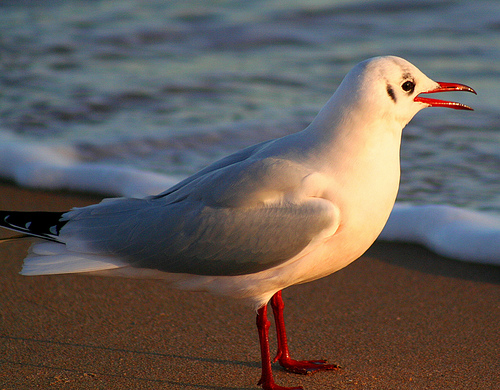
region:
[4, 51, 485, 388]
red-billed gull aka mackerel gull or tarapunga or akiaki. you asked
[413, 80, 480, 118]
red beak, looks bloody, probably isnt. born like that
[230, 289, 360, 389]
a fancy pair of bright red legs if you ask me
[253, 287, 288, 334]
knobby knees, kinda like a giraffe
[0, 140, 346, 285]
grey wings, black wingtips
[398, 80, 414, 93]
dark eye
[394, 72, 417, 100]
dark red ring around eye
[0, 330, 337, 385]
long thin shadow of longish thinnish red legs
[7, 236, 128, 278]
reasonably short straight-end white tail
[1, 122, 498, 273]
seabird gazes a little above the seafoam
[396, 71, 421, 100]
a bird's right eye.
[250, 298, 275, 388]
a right bird leg.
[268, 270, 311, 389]
a left bird leg.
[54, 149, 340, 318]
a right bird wing.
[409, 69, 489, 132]
an orange bird beak.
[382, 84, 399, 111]
a black spot on a bird.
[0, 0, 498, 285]
a small body of water.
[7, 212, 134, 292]
tail feathers on a bird.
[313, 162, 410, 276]
a chest on a bird.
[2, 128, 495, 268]
a foamy wave.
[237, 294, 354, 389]
The red feet of a bird.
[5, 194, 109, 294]
A black tail of a bird.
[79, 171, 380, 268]
Gray wings of white and gray bird.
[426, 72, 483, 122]
This bird has a red beak.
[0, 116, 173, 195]
Foam is on the water wave.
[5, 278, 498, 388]
The bird is standing on a sandy beach.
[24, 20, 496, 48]
Waves are formed in the water.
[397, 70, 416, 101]
This bird has black eyes.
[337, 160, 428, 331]
The bird has a white belly.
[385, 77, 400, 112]
There is a black spot on the bird's head.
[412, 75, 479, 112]
seagull's open beak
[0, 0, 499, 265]
slightly small waves along the shore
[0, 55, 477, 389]
white seagull calling out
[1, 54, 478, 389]
seagull walking on the sand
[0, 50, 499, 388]
seagull walking close to the waters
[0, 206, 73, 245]
seagull's black tail feather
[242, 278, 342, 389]
seagull's reddish and orange feet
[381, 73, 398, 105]
dark mark on the seagull's face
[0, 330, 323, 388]
shadow of the seagull's legs and feet on the sand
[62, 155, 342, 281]
black and white wing of the seagull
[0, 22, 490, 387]
A seagull is standing on the beach.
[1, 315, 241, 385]
A shadow of the bird's legs.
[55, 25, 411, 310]
The bird has a white body.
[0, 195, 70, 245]
The bird has black and white tail feathers.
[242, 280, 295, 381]
The bird has orange legs.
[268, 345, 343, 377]
The seagull has an orange foot.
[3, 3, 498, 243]
Water in the ocean.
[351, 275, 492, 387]
Sand on the beach.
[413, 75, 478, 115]
The bird has an orange beak.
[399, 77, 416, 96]
The seagull has a black colored eye.